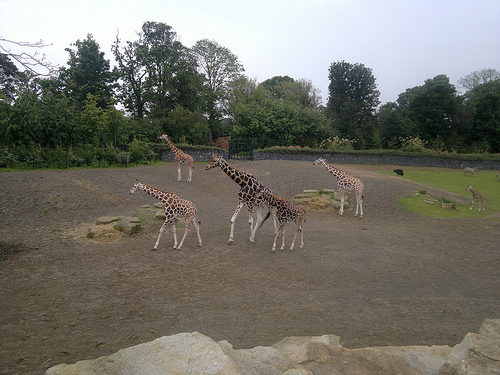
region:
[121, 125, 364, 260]
The giraffes on the dirt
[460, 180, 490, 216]
The giraffe on the grass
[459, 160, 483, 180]
The zebra on the grass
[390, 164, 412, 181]
The large black bird on the grass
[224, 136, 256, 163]
The black gate in the stone wall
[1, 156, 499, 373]
The large dirt field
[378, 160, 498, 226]
The grass portion of the field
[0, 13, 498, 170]
The trees behind the stone wall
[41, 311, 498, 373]
The large rock formation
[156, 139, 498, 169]
The stone wall at the field's edge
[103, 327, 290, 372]
grey rock surface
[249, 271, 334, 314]
patch of bron dirt on ground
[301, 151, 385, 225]
one giraffe standing on patch of dirt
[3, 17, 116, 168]
trees and foliage on outskirts of dirt field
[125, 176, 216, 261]
giraffe walking on dirt ground toward the left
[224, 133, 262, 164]
black fence in between two rock barriers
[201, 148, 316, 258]
adult giraffe walking next to juvenile giraffe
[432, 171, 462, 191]
patch of green grass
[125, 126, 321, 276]
four giraffes walking across dirt field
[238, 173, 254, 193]
brown and tan spots on giraffe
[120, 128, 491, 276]
Multiple giraffes in a zoo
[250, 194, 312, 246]
A young giraffe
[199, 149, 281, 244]
Adult giraffe by young giraffe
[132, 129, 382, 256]
The giraffes are yellow and brown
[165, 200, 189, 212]
Brown spots on the giraffe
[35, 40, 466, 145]
Green trees in the distance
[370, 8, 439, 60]
The open blue sky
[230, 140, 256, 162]
A black gate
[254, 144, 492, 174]
A small stone wall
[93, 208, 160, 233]
A rocky outcropping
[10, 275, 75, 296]
FIELD IS FULL OF DIRT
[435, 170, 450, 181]
grass is very full and thick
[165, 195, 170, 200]
brown spots on the giraffe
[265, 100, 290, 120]
trees are very tall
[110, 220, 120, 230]
a rock laying on the ground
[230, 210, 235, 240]
giraffe leg is white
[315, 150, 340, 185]
the giraffe neck is long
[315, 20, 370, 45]
sky is very cloudy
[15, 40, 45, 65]
branches are empty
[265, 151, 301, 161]
brick wall along the edge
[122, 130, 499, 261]
six giraffes are in a pen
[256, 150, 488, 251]
little baby giraffes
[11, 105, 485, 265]
mom giraffes and baby giraffes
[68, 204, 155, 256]
rocks that sit inside the area for the giraffes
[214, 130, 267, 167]
a gate for the pen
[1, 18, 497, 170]
The tree line that is outside of the pen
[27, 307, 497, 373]
rocks that outside of the pen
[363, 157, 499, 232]
a green patch of grass inside the pen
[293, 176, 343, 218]
a pile of rocks and grass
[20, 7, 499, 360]
the mom and baby giraffes walking around their pen